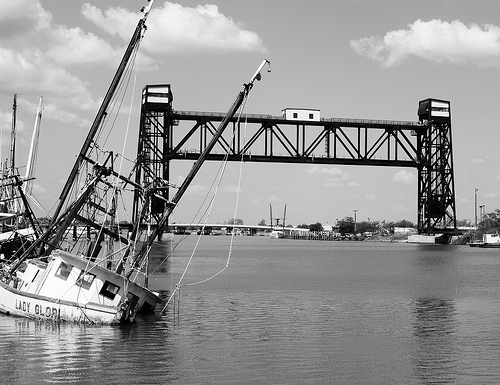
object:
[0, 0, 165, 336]
ship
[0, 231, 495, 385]
water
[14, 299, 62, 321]
lady glori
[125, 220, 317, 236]
pier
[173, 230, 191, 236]
boats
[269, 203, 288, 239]
crane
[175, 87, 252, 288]
ropes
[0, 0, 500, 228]
sky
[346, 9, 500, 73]
clouds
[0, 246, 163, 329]
boats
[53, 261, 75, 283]
windows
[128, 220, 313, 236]
bridge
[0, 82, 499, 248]
background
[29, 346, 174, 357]
ripples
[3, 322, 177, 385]
shadow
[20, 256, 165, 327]
front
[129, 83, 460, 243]
bridge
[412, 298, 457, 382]
shadow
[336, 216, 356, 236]
trees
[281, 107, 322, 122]
building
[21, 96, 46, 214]
sail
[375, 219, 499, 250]
bank